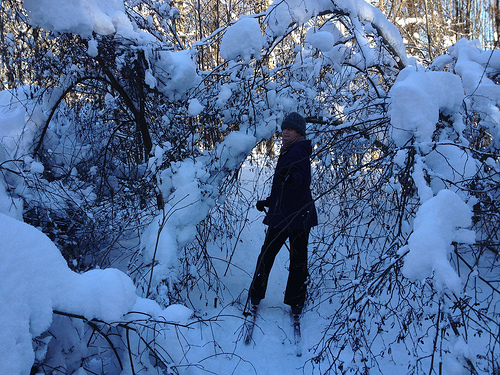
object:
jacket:
[268, 150, 318, 229]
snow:
[4, 229, 193, 325]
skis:
[243, 292, 302, 356]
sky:
[396, 2, 496, 43]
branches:
[11, 48, 157, 173]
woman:
[244, 109, 313, 314]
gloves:
[257, 166, 297, 215]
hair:
[280, 133, 301, 150]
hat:
[280, 113, 308, 128]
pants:
[246, 225, 306, 303]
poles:
[255, 206, 297, 265]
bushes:
[5, 158, 164, 260]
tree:
[1, 2, 191, 187]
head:
[281, 124, 294, 136]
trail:
[226, 158, 322, 373]